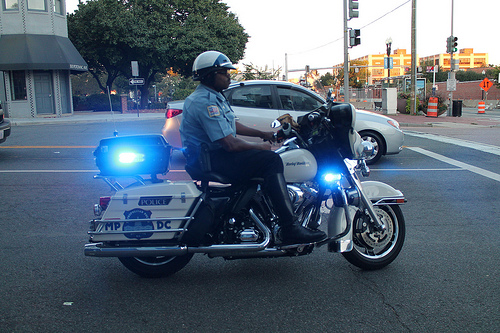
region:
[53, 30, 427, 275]
cop on a motorcycle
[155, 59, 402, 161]
car waiting at a traffic light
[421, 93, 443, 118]
orange construction barrel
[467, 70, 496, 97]
orange construction sign giving directions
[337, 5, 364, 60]
traffic signal on a pole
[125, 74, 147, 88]
One Way arrow traffic sign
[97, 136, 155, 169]
blue light on a motorcycle of a traffic cop's vehicle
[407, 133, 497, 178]
painted lines of a crosswalk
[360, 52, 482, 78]
brick building son the background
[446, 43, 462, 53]
green light of a traffic signal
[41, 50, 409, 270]
Police man on bike waiting at traffic signal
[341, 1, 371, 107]
Traditional traffic signal light pole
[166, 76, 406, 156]
Fullsized Sedan waiting for traffic signal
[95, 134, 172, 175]
Bike patrol trunk case with blue flash light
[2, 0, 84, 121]
Apartment at the side road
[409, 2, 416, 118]
Overhead power line pole closer to traffic signal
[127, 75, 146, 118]
Post mount one way sign board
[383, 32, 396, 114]
Modern looking street lamps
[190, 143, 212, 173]
A cpative bolt on it case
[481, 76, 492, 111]
A two traffic road work sign at the side road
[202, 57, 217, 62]
A protective head gear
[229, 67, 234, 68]
A visa on the helmet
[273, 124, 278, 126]
A side mirror on the motorbike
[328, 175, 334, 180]
A flashing light in front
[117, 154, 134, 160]
A flashing light in the rear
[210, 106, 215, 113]
A badge on the shoulder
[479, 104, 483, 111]
A marked reflective barrier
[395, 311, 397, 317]
A crack on the road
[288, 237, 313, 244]
Shoe on the motorbike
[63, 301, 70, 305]
A whitish spot on the road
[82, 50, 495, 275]
road patrol wait for his green signal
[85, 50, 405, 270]
road patrol sitting in his motor cycle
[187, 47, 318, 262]
a road patrol with his white helmet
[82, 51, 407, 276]
a car is waiting by the side of road patrol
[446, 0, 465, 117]
a road signal showing its green light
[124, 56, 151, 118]
a sign board on the road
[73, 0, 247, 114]
grown trees with green leaves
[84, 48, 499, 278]
a car and a motor cycle waiting for green signal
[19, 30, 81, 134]
door is closed in the building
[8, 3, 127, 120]
there is a tree near the building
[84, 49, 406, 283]
a police on his motorcycle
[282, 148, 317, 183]
the gas tank of the motorcycle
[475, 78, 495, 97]
a traffic sign in the distance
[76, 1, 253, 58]
a leafy tree in the backgrounnd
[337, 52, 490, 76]
a couple of big buildings in the distance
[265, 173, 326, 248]
the police black boot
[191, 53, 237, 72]
the police helmet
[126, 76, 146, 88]
an arrow indicating to the left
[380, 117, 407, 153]
the frontal part of the car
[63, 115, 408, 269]
the police white motorcycle